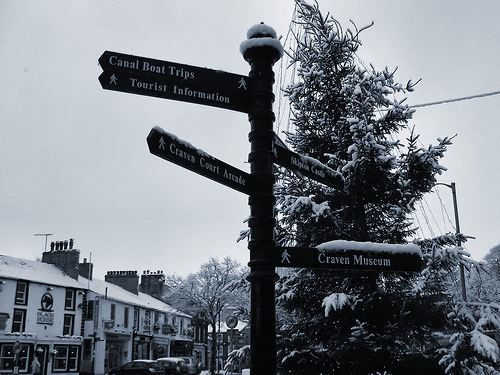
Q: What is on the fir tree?
A: Snow.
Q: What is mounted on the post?
A: Signs for tourists.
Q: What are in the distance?
A: White buildings.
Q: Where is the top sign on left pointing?
A: To boat trips and tourist info.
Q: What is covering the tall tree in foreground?
A: Snow.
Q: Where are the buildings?
A: On left side.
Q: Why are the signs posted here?
A: To show directions.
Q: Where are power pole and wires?
A: On right side of tall tree.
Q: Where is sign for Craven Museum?
A: Lower right side of pole.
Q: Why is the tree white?
A: It's overed in snow.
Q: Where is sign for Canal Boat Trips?
A: Top sign on left of pole.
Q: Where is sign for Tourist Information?
A: Top sign on left of pole.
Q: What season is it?
A: Winter.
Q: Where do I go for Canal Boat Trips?
A: To the left.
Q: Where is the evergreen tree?
A: Behind the sign.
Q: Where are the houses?
A: On the left.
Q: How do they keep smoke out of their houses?
A: Chimneys.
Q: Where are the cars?
A: In front of the houses.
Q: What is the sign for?
A: Directions.